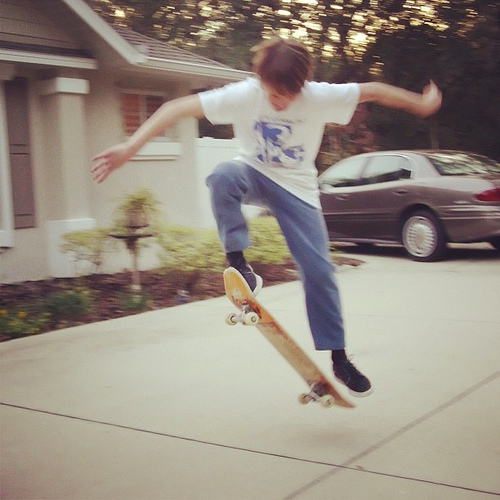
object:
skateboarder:
[91, 40, 441, 408]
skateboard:
[222, 267, 354, 412]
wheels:
[244, 312, 259, 328]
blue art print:
[253, 114, 312, 175]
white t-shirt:
[196, 77, 359, 210]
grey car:
[318, 149, 499, 261]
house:
[1, 0, 258, 281]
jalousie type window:
[120, 92, 169, 140]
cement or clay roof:
[112, 24, 235, 68]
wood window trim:
[3, 79, 36, 229]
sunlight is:
[115, 0, 496, 38]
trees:
[313, 0, 500, 78]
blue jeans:
[199, 158, 345, 352]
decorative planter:
[109, 190, 156, 301]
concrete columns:
[39, 70, 101, 278]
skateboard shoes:
[333, 358, 372, 396]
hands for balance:
[91, 144, 130, 185]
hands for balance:
[312, 79, 444, 119]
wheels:
[400, 210, 447, 263]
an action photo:
[0, 0, 499, 499]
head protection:
[254, 39, 310, 111]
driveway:
[0, 242, 499, 499]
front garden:
[2, 259, 365, 343]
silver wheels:
[393, 205, 441, 265]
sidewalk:
[130, 267, 475, 479]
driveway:
[356, 243, 485, 272]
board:
[218, 263, 354, 415]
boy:
[87, 44, 443, 408]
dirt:
[67, 271, 208, 300]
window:
[115, 93, 179, 163]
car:
[295, 142, 498, 256]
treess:
[361, 35, 479, 150]